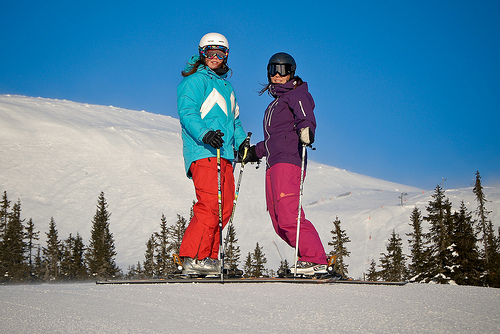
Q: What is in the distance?
A: Green trees.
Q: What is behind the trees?
A: Snow covered mountain.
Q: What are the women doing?
A: Posing for a picture.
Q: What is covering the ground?
A: Snow.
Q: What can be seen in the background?
A: Trees.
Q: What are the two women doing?
A: Posing for a picture.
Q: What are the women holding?
A: Ski poles.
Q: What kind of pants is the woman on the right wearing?
A: Pink snowpants.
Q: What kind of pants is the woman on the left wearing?
A: Red snow pants.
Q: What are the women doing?
A: Skiing.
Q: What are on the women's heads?
A: Helmets.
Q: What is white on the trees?
A: Snow.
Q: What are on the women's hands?
A: Gloves.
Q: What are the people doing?
A: Skiing.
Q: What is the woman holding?
A: Poles.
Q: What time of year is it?
A: Winter.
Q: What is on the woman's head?
A: A helmet.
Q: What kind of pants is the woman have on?
A: Ski pants.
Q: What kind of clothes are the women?
A: Ski clothes.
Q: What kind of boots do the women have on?
A: Ski boots.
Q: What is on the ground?
A: Snow.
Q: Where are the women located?
A: A ski mountain.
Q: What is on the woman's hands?
A: Ski gloves.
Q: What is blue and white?
A: Coat.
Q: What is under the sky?
A: Mountains.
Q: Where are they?
A: On snow.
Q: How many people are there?
A: Two.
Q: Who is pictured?
A: Two girls.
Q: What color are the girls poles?
A: White and black.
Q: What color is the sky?
A: Blue.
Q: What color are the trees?
A: Green.